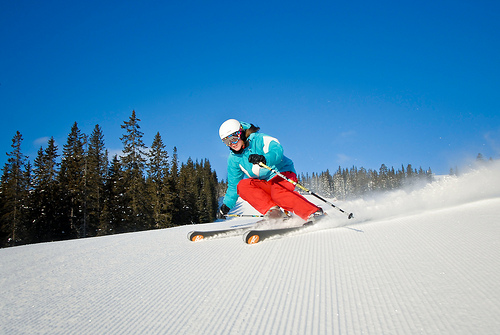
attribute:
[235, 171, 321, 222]
pants — red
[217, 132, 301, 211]
coat — blue, white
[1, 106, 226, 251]
pine trees — in a group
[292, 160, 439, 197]
pine trees — in a group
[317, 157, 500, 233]
snow — being blown up, white, clear, kicked up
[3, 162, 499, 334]
slope — white, snowy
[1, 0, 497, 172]
sky — bright blue, clear, deep bright blue, cloudless, blue, bright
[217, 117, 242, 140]
helmet — white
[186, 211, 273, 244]
ski — black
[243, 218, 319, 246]
ski — black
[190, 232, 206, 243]
circle — orange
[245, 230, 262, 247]
circle — orange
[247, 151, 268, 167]
glove — black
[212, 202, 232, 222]
glove — black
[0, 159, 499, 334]
snow — smooth, perfectly raked, white, clear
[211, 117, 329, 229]
girl — skiing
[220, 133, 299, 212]
jacket — blue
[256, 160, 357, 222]
ski pole — black, white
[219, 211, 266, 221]
ski pole — black, white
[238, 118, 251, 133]
hair tie — blue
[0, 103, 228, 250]
evergreen trees — tall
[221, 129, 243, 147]
snow goggles — colorful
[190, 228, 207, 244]
pattern — circular, orange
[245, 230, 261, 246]
pattern — circular, orange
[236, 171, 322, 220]
ski pants — red-orange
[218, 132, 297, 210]
ski jacket — aqua blue, white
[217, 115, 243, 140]
ski helmet — white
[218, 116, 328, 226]
woman — skiing downhill, young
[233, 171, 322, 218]
snow pants — red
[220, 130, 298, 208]
snow jacket — aqua blue